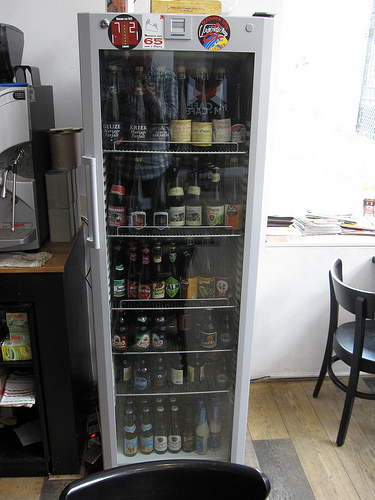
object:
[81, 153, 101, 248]
handle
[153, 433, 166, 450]
label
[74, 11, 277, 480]
cooler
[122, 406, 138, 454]
bottles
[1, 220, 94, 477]
table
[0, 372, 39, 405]
towels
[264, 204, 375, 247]
shelf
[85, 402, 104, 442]
outlet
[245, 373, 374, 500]
floor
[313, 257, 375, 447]
chair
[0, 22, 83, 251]
machine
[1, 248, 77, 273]
counter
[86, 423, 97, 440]
light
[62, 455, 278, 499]
chair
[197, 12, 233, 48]
stickers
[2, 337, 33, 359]
tea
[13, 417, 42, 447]
napkin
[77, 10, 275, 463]
door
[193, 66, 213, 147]
beverages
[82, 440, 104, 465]
strip